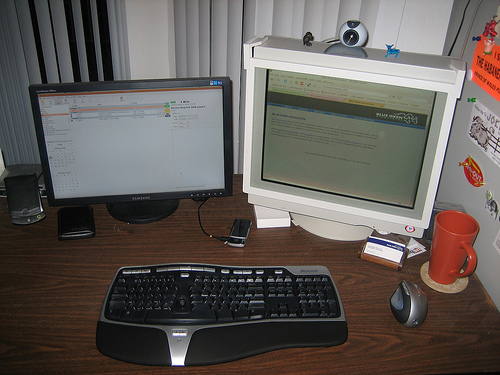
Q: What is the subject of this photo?
A: Computer equipment.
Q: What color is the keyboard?
A: Black and silver.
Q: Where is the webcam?
A: On top of the monitor on the right.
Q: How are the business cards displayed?
A: In a holder next to the coffee cup.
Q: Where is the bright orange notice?
A: Posted on the wall on the right.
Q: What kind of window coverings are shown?
A: Vertical blinds.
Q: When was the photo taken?
A: At night.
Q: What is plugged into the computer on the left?
A: A cell phone.